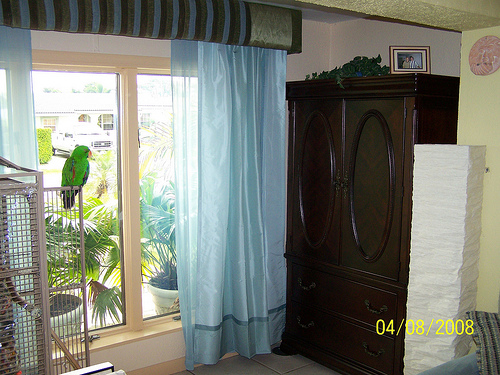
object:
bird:
[56, 145, 94, 209]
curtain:
[171, 38, 288, 372]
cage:
[0, 155, 90, 374]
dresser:
[285, 73, 458, 374]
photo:
[391, 44, 433, 76]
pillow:
[464, 310, 499, 375]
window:
[1, 41, 267, 356]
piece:
[87, 279, 126, 329]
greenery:
[41, 196, 126, 328]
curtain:
[0, 25, 40, 374]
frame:
[389, 45, 431, 75]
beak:
[87, 148, 92, 160]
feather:
[73, 158, 87, 186]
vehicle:
[51, 118, 117, 160]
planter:
[50, 292, 84, 340]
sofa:
[419, 352, 482, 375]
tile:
[240, 348, 317, 375]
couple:
[401, 55, 420, 69]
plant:
[306, 55, 393, 90]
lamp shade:
[404, 143, 484, 372]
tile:
[184, 354, 278, 375]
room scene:
[0, 0, 499, 374]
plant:
[138, 172, 225, 320]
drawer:
[288, 261, 402, 337]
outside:
[2, 70, 198, 337]